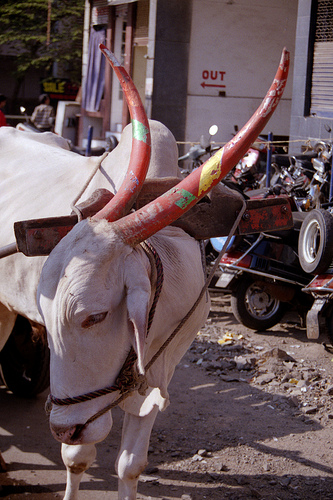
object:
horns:
[90, 41, 153, 226]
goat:
[0, 41, 290, 499]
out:
[200, 68, 229, 83]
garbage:
[231, 352, 259, 376]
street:
[0, 284, 332, 498]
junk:
[260, 174, 313, 212]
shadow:
[0, 337, 332, 499]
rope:
[142, 241, 164, 337]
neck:
[123, 238, 157, 387]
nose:
[49, 420, 81, 445]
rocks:
[195, 445, 208, 460]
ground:
[0, 280, 332, 499]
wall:
[182, 0, 297, 173]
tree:
[0, 0, 88, 105]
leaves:
[17, 15, 24, 22]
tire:
[295, 208, 326, 275]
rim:
[301, 214, 320, 264]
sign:
[43, 81, 68, 95]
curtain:
[308, 0, 333, 108]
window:
[303, 0, 333, 123]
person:
[0, 96, 8, 128]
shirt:
[0, 115, 8, 127]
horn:
[114, 44, 289, 246]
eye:
[80, 311, 108, 330]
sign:
[200, 67, 228, 89]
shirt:
[32, 102, 54, 131]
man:
[28, 94, 58, 132]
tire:
[230, 281, 285, 331]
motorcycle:
[213, 198, 333, 334]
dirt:
[0, 280, 332, 499]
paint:
[197, 143, 223, 196]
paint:
[169, 186, 195, 209]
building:
[78, 2, 298, 160]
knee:
[110, 455, 142, 484]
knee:
[58, 444, 90, 480]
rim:
[245, 287, 278, 320]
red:
[226, 141, 243, 165]